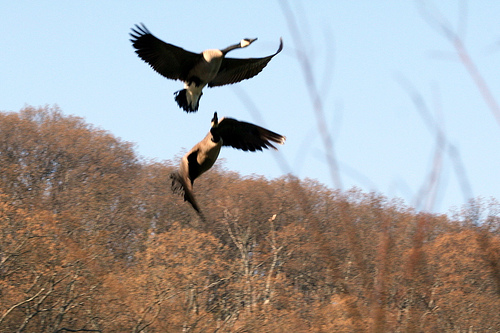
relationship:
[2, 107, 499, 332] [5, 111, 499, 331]
trees with leaves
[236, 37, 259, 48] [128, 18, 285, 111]
head of goose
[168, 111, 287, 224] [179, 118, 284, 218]
bird flapping wings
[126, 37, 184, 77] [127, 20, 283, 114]
wing of bird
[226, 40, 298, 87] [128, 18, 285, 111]
left wing of goose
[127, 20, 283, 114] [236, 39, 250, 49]
bird has a cheek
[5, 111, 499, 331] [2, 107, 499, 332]
leaves of trees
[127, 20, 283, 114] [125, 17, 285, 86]
bird with wings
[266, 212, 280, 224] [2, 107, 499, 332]
bird sitting in trees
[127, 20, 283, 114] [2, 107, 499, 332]
bird sitting in trees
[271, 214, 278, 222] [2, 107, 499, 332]
bird sitting in trees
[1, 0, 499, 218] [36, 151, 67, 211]
sky peeking through branches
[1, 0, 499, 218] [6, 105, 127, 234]
sky peeking through tree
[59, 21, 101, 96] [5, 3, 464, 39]
clouds in sky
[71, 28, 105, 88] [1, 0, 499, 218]
clouds in sky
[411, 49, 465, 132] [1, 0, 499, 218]
clouds in sky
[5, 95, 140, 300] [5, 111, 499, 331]
trees with leaves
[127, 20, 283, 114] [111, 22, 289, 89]
bird with wings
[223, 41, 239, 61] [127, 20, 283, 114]
neck of bird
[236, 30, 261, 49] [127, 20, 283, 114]
head of bird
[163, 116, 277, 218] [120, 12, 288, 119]
bird beneath bird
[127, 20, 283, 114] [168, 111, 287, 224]
bird chasing bird